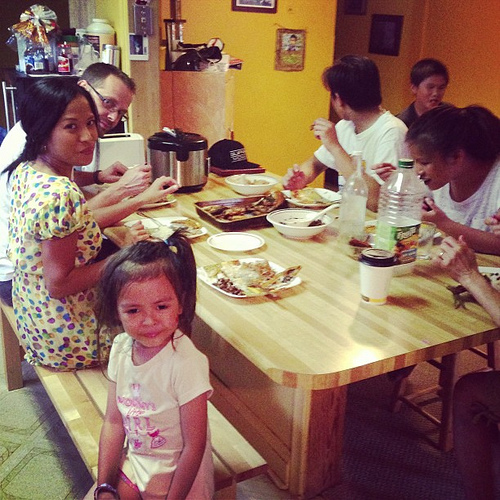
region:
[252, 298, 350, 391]
this is a table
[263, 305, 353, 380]
the table is wooden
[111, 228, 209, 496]
this is a child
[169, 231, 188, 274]
this is the hair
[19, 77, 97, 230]
this is a lady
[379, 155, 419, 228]
this is a bottle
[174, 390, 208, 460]
this is a hand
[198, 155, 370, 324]
the table is full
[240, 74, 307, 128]
this is the wall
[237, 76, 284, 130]
the wall is cream in color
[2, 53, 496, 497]
people sitting at table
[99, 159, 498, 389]
food on wood table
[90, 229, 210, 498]
girl with hair in pony tail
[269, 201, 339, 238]
white spoon in bowl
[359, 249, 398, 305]
paper cup with lid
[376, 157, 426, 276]
plastic bottle with ribbed surface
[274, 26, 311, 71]
picture hanging on wall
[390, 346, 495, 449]
wood legs of chair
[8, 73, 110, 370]
woman in polka dot dress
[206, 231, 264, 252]
empty plate on table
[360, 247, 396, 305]
A paper cup on the table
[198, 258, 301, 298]
A square plate of food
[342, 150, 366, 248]
A glass bottle on the table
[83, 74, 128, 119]
Eyeglasses on a man's face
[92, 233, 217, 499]
A little girl in a pink shirt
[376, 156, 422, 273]
A plastic bottle on the table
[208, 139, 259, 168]
A black hat at the table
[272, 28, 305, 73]
A picture hanging on a yellow wall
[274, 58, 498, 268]
People sitting at the table, eating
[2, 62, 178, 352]
People sitting at the table, eating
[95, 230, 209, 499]
a young girl in pink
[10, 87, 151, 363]
a woman is sitting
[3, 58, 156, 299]
a man is sitting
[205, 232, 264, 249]
white plate on a table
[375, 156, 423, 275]
a large plastic jug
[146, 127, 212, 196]
a black and metal rice cooker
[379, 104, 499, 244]
a woman is eating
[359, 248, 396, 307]
a cup on a table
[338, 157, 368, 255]
a plastic bottle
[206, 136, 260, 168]
a black hat with white design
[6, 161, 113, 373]
white and multicolored dress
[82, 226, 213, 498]
little girl sitting on a bench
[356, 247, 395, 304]
coffee cup with travel lid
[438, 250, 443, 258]
gold wedding ring on finger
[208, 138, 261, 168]
black baseball cap withwhite writing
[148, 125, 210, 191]
black and silver rice cooker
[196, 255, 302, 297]
square plate with food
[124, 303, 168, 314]
two dark eyes on a child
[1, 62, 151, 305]
man in glasses eating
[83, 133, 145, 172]
white colored toaster for bread